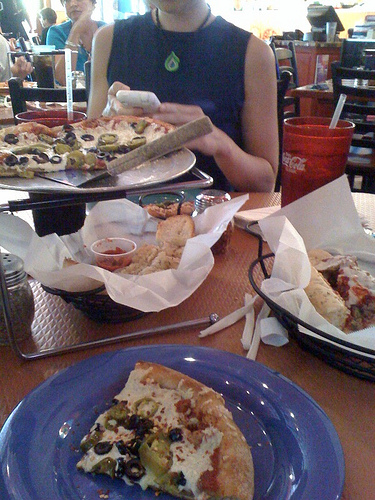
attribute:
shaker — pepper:
[191, 190, 232, 254]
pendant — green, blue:
[158, 52, 186, 72]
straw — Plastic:
[323, 88, 347, 127]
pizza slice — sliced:
[72, 355, 258, 497]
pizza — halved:
[12, 117, 168, 181]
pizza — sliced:
[88, 368, 278, 498]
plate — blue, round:
[13, 344, 353, 498]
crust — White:
[134, 359, 254, 498]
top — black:
[82, 17, 269, 159]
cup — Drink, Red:
[279, 115, 357, 210]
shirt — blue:
[45, 19, 106, 72]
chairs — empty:
[273, 28, 373, 158]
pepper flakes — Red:
[162, 442, 204, 467]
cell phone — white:
[113, 86, 164, 115]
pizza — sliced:
[72, 352, 263, 499]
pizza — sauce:
[9, 93, 179, 168]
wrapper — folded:
[198, 291, 259, 349]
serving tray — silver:
[2, 143, 206, 192]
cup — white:
[28, 42, 59, 87]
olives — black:
[32, 150, 63, 165]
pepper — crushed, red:
[217, 228, 229, 253]